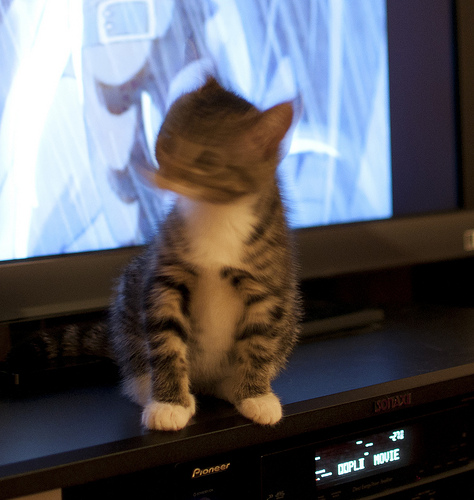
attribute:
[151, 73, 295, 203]
face — blurry, cat's, in motion, his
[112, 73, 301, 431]
kitten — gray, striped, grey, black, white, shaking, white pawed, furry, sitting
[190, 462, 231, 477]
brand — silver colored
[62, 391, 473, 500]
vcr — on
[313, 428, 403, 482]
lights — lit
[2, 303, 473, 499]
table — brown, wooden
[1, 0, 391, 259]
movie — being shown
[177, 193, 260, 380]
belly — white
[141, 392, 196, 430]
paw — white, cat's, front left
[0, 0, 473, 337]
television — on, flat screen, large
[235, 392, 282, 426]
paw — white, cat's, front right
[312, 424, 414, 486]
display — lcd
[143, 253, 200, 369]
stripes — black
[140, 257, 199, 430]
leg — front left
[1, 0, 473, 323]
encasing — plastic, gray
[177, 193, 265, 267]
patch — white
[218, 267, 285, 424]
leg — front right